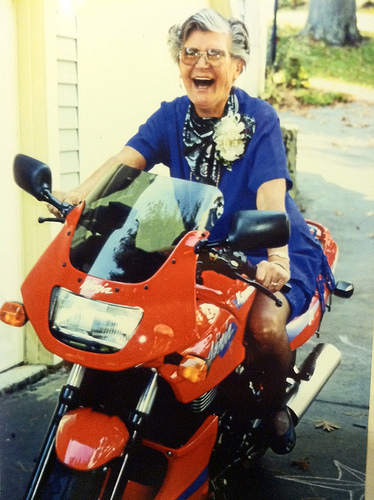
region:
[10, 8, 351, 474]
an older woman sitting on a motorcycle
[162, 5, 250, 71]
the womans gray hair is fingerwaved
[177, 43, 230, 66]
glasses that are tinted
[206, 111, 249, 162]
a corsage on the woman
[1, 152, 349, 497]
a red motocycle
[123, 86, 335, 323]
the womans blue dress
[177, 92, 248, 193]
a black and white neck scarf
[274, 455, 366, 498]
lines of chalk on the concrete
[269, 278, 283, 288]
the womans ring on her finger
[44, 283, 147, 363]
the front light on the motorcyle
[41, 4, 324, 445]
a woman sitting down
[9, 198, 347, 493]
an orange red motorcycle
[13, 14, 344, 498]
a woman riding a motorcycle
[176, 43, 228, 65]
a pair of eyeglasses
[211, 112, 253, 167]
a white flower corsage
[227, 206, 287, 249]
a left rearview mirror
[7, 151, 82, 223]
a right rearview mirror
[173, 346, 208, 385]
a left turn signal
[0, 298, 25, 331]
a right turn signal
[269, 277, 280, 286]
a woman's wedding ring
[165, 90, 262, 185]
white flower on a lady's shirt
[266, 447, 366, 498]
a chalk drawing on the ground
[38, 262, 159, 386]
a headlight on the bike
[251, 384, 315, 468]
black women's shoe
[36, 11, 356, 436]
a woman riding a motorcyle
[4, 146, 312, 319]
handlebars on the bike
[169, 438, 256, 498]
a blue stripe on a red bike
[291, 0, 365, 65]
a brown tree trunk in the grass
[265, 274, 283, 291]
a ring on a woman's hand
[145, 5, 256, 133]
a woman with gray hair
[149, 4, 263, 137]
a woman wearing glasses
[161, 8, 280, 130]
a woman with grey hair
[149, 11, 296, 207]
a woman with a white flower on her dress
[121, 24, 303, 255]
a woman wearing a blue dress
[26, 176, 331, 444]
a red motorcycle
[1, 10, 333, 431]
a woman on a red motorcycle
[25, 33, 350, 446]
a red motorcycle with a woman on it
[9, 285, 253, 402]
orange head lights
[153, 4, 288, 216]
a woman smiling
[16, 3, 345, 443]
a yellow house with white doors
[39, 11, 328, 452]
the old lady on the bike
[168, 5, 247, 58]
the gray hair on the lady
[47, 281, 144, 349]
the white light on the front of the bike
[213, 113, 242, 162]
the flowers on her chest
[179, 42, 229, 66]
the lady's eye glasses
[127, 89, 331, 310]
the lady's blue outfit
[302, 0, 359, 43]
the tree trunk in the back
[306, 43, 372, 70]
the grass in front of the tree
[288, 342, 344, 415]
the muffler on the motorcycle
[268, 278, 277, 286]
the ring on the lady's finger